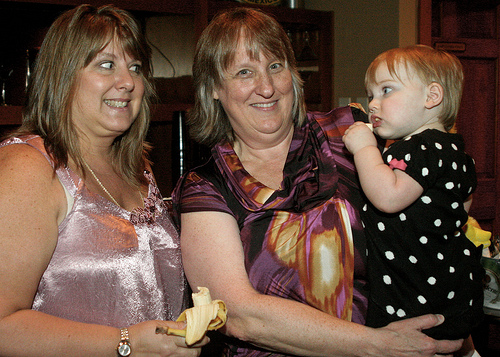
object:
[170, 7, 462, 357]
woman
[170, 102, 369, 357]
shirt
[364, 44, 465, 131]
hair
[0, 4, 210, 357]
woman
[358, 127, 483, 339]
dress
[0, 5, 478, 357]
three people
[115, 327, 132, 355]
watch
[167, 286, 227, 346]
banana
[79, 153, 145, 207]
necklace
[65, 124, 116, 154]
neck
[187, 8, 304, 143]
hair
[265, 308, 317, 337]
freckles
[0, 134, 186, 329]
shirt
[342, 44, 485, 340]
baby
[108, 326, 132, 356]
wrist